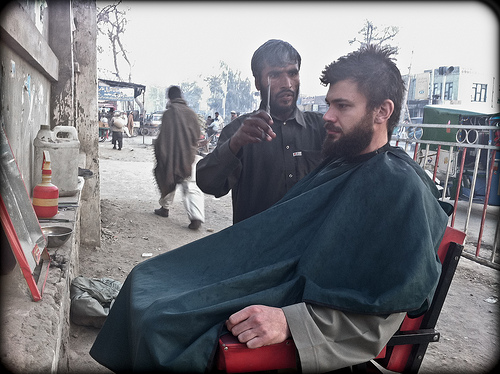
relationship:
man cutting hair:
[193, 39, 331, 256] [250, 41, 300, 68]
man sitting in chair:
[123, 47, 429, 374] [210, 226, 467, 374]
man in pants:
[153, 86, 206, 230] [159, 148, 204, 219]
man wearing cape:
[123, 47, 429, 374] [115, 163, 420, 371]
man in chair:
[123, 47, 429, 374] [216, 226, 466, 372]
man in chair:
[123, 47, 429, 374] [211, 224, 461, 364]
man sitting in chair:
[285, 52, 408, 212] [380, 260, 438, 369]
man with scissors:
[203, 41, 343, 256] [250, 67, 286, 144]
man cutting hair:
[193, 39, 331, 256] [317, 37, 411, 142]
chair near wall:
[211, 224, 461, 364] [16, 232, 72, 364]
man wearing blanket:
[153, 84, 201, 230] [151, 96, 203, 198]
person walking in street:
[100, 102, 150, 160] [101, 149, 174, 252]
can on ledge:
[30, 147, 60, 217] [1, 171, 88, 371]